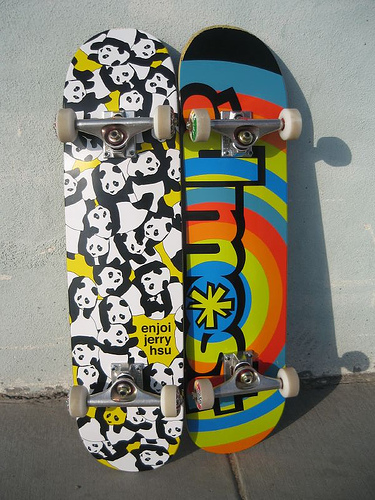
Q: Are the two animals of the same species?
A: Yes, all the animals are bears.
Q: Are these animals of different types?
A: No, all the animals are bears.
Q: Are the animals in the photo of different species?
A: No, all the animals are bears.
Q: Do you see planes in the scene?
A: No, there are no planes.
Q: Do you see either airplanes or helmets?
A: No, there are no airplanes or helmets.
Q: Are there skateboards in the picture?
A: Yes, there is a skateboard.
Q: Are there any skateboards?
A: Yes, there is a skateboard.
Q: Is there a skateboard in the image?
A: Yes, there is a skateboard.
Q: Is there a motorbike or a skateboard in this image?
A: Yes, there is a skateboard.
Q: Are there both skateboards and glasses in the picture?
A: No, there is a skateboard but no glasses.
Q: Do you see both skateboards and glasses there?
A: No, there is a skateboard but no glasses.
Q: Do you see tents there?
A: No, there are no tents.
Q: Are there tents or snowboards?
A: No, there are no tents or snowboards.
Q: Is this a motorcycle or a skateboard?
A: This is a skateboard.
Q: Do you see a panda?
A: Yes, there is a panda.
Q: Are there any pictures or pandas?
A: Yes, there is a panda.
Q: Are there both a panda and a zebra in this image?
A: No, there is a panda but no zebras.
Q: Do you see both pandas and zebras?
A: No, there is a panda but no zebras.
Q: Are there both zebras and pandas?
A: No, there is a panda but no zebras.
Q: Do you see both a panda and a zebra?
A: No, there is a panda but no zebras.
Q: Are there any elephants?
A: No, there are no elephants.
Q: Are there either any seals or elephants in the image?
A: No, there are no elephants or seals.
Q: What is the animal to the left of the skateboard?
A: The animal is a panda.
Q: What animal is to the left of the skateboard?
A: The animal is a panda.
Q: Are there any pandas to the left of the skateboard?
A: Yes, there is a panda to the left of the skateboard.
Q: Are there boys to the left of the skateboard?
A: No, there is a panda to the left of the skateboard.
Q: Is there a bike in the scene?
A: No, there are no bikes.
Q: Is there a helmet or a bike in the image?
A: No, there are no bikes or helmets.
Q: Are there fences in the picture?
A: No, there are no fences.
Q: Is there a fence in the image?
A: No, there are no fences.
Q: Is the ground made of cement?
A: Yes, the ground is made of cement.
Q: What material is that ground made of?
A: The ground is made of concrete.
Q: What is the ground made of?
A: The ground is made of concrete.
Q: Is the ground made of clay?
A: No, the ground is made of cement.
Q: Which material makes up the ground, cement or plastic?
A: The ground is made of cement.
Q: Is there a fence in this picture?
A: No, there are no fences.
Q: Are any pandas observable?
A: Yes, there is a panda.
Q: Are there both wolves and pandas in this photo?
A: No, there is a panda but no wolves.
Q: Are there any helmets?
A: No, there are no helmets.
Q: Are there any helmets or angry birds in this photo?
A: No, there are no helmets or angry birds.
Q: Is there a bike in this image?
A: No, there are no bikes.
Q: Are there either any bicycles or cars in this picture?
A: No, there are no bicycles or cars.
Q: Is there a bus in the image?
A: No, there are no buses.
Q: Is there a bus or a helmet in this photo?
A: No, there are no buses or helmets.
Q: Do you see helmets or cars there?
A: No, there are no helmets or cars.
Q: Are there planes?
A: No, there are no planes.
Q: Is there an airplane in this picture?
A: No, there are no airplanes.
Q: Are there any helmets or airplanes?
A: No, there are no airplanes or helmets.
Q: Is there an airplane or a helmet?
A: No, there are no airplanes or helmets.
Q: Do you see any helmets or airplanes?
A: No, there are no airplanes or helmets.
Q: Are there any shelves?
A: No, there are no shelves.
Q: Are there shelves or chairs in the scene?
A: No, there are no shelves or chairs.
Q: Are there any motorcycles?
A: No, there are no motorcycles.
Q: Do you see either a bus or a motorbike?
A: No, there are no motorcycles or buses.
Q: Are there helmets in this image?
A: No, there are no helmets.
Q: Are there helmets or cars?
A: No, there are no helmets or cars.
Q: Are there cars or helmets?
A: No, there are no helmets or cars.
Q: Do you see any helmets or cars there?
A: No, there are no helmets or cars.